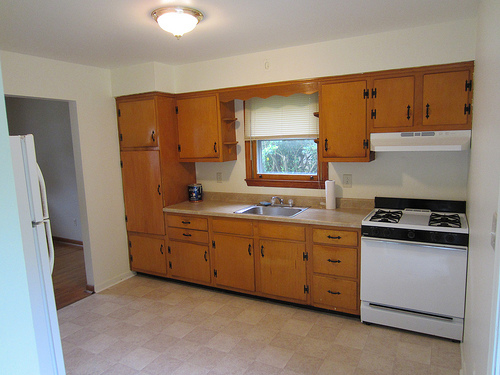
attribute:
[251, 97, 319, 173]
window — open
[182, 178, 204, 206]
coffee machine — pictured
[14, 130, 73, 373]
refrigerator — small, white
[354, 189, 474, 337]
stove — white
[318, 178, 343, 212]
paper towels — roll, white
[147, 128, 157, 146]
cabinet handle — black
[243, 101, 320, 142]
window shade — beige-colored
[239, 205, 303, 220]
sink — stainless steel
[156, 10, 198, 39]
light — on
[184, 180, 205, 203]
tin can — blue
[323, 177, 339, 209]
paper — white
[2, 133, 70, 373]
fridge — white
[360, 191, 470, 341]
stove — black and white, white and black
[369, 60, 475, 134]
cabinet — brown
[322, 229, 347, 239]
knob — black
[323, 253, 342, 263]
knob — black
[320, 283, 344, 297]
knob — black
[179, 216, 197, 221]
knob — black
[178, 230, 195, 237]
knob — black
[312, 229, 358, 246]
drawer — brown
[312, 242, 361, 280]
drawer — brown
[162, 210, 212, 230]
drawer — brown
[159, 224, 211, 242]
drawer — brown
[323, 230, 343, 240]
knob — black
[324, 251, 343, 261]
knob — black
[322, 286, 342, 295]
knob — black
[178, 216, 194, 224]
knob — black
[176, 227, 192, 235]
knob — black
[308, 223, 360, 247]
drawer — brown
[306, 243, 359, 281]
drawer — brown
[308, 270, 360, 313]
drawer — brown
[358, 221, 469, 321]
oven — black and white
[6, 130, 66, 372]
refrigerator — white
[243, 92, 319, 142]
blinds — white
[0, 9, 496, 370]
wall — white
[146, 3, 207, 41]
light — bright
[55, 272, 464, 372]
floor — tiled, beige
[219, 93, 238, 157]
shelves — small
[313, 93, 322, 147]
shelves — small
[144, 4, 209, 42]
dome light — overhead